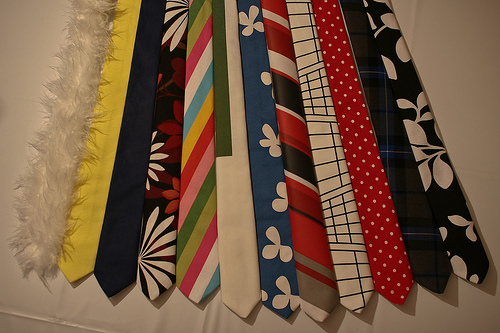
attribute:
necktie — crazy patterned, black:
[364, 0, 490, 282]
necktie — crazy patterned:
[339, 0, 449, 297]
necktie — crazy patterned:
[310, 1, 411, 306]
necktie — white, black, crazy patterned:
[284, 2, 373, 316]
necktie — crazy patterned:
[258, 1, 339, 325]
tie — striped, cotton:
[171, 0, 218, 310]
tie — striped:
[241, 2, 332, 307]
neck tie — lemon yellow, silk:
[54, 0, 145, 287]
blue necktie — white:
[235, 5, 304, 321]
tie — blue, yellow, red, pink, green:
[160, 3, 231, 313]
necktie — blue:
[237, 0, 301, 321]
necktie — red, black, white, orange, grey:
[236, 126, 366, 254]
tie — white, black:
[289, 2, 396, 331]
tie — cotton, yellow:
[48, 1, 144, 259]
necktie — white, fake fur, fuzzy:
[11, 2, 123, 291]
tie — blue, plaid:
[339, 0, 452, 295]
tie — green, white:
[204, 1, 267, 321]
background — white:
[0, 0, 499, 327]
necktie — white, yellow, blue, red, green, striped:
[173, 2, 218, 306]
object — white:
[436, 213, 479, 285]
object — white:
[393, 84, 453, 194]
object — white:
[358, 3, 412, 84]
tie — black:
[95, 2, 164, 298]